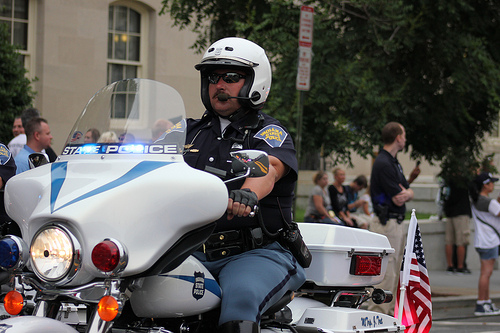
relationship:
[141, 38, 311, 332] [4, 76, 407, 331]
policeman on motorcycle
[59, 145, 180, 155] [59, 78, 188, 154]
logo on windshield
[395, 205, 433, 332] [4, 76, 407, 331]
flag on motorcycle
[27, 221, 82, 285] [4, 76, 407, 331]
headlight on motorcycle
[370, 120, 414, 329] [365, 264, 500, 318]
man on curb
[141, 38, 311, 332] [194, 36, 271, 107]
policeman wearing helmet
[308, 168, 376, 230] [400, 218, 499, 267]
people on wall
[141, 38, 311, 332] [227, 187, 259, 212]
policeman wearing gloves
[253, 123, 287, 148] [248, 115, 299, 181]
patch on sleeve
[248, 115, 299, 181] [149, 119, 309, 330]
sleeve on uniform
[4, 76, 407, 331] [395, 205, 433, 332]
motorcycle has flag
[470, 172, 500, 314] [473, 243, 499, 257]
female wearing shorts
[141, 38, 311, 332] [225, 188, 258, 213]
policeman wearing glove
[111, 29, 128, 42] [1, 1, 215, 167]
light inside building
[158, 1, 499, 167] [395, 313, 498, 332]
tree by street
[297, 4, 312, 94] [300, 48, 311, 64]
signs say no parking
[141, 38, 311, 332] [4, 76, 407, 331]
policeman riding motorcycle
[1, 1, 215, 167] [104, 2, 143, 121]
building has window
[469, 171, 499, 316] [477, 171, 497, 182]
woman has hat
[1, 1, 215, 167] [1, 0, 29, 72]
building has window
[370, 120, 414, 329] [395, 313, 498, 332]
man by street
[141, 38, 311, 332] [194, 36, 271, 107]
policeman has helmet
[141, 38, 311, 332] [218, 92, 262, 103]
policeman has speaker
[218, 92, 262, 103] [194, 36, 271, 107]
speaker on helmet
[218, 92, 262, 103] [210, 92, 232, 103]
speaker by mouth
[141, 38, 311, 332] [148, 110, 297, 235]
policeman has shirt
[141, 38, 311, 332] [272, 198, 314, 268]
policeman has walkie talkie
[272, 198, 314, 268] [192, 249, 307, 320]
walkie talkie on pants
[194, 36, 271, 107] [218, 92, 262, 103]
helmet has microphone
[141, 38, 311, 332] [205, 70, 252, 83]
policeman wearing sunglasses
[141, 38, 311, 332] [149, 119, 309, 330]
policeman in uniform